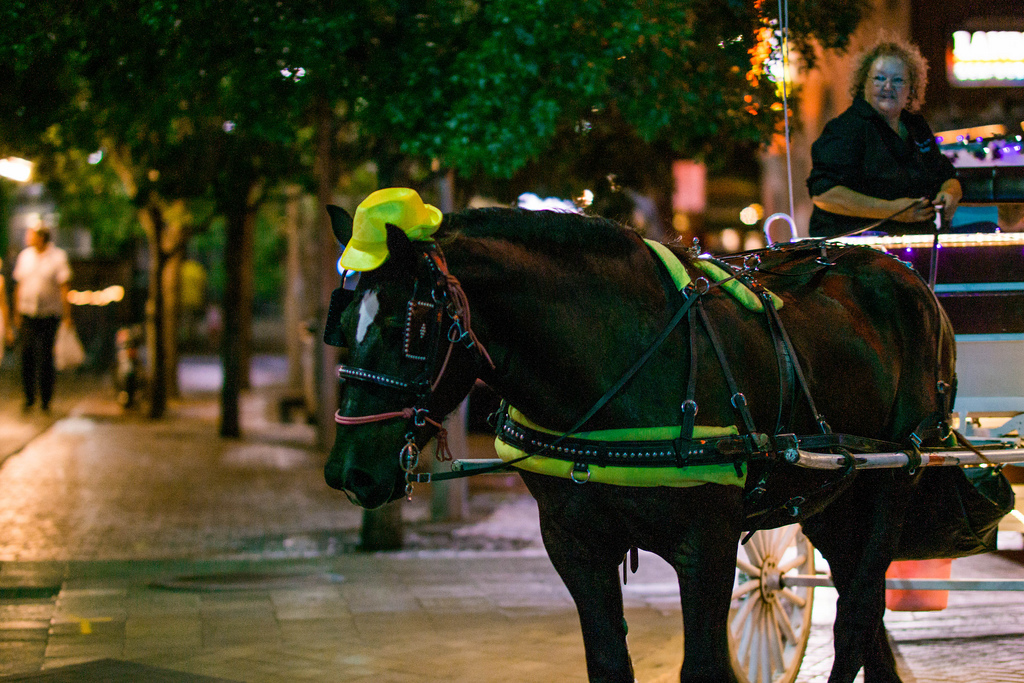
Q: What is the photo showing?
A: It is showing a street.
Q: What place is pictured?
A: It is a street.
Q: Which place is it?
A: It is a street.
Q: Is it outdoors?
A: Yes, it is outdoors.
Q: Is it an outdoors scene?
A: Yes, it is outdoors.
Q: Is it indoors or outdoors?
A: It is outdoors.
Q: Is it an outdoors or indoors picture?
A: It is outdoors.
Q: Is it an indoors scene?
A: No, it is outdoors.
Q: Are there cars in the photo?
A: No, there are no cars.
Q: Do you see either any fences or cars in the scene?
A: No, there are no cars or fences.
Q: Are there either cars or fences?
A: No, there are no cars or fences.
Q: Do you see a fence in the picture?
A: No, there are no fences.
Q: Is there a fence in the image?
A: No, there are no fences.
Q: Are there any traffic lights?
A: No, there are no traffic lights.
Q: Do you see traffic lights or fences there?
A: No, there are no traffic lights or fences.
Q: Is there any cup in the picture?
A: No, there are no cups.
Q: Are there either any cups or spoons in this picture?
A: No, there are no cups or spoons.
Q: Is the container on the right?
A: Yes, the container is on the right of the image.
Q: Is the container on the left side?
A: No, the container is on the right of the image.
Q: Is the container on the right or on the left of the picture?
A: The container is on the right of the image.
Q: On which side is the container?
A: The container is on the right of the image.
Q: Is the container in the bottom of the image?
A: Yes, the container is in the bottom of the image.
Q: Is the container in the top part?
A: No, the container is in the bottom of the image.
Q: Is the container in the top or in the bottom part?
A: The container is in the bottom of the image.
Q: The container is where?
A: The container is on the street.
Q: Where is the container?
A: The container is on the street.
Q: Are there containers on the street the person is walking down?
A: Yes, there is a container on the street.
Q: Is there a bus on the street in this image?
A: No, there is a container on the street.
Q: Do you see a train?
A: No, there are no trains.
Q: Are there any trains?
A: No, there are no trains.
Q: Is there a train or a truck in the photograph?
A: No, there are no trains or trucks.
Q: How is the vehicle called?
A: The vehicle is a carriage.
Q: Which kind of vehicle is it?
A: The vehicle is a carriage.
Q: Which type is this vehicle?
A: That is a carriage.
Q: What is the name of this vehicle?
A: That is a carriage.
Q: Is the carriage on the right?
A: Yes, the carriage is on the right of the image.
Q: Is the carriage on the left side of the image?
A: No, the carriage is on the right of the image.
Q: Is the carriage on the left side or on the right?
A: The carriage is on the right of the image.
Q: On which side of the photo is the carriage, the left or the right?
A: The carriage is on the right of the image.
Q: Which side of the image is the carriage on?
A: The carriage is on the right of the image.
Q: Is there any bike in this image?
A: No, there are no bikes.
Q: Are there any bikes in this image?
A: No, there are no bikes.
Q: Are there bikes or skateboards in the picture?
A: No, there are no bikes or skateboards.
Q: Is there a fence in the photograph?
A: No, there are no fences.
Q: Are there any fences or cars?
A: No, there are no fences or cars.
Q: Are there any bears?
A: No, there are no bears.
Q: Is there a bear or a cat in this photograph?
A: No, there are no bears or cats.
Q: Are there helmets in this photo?
A: No, there are no helmets.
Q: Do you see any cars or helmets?
A: No, there are no helmets or cars.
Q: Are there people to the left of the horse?
A: Yes, there is a person to the left of the horse.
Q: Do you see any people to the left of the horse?
A: Yes, there is a person to the left of the horse.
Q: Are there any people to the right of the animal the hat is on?
A: No, the person is to the left of the horse.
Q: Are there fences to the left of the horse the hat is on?
A: No, there is a person to the left of the horse.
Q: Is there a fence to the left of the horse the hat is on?
A: No, there is a person to the left of the horse.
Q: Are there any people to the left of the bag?
A: Yes, there is a person to the left of the bag.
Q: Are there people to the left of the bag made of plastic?
A: Yes, there is a person to the left of the bag.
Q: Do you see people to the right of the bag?
A: No, the person is to the left of the bag.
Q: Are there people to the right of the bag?
A: No, the person is to the left of the bag.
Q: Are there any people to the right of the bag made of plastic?
A: No, the person is to the left of the bag.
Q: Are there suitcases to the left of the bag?
A: No, there is a person to the left of the bag.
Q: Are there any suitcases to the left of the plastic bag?
A: No, there is a person to the left of the bag.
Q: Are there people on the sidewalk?
A: Yes, there is a person on the sidewalk.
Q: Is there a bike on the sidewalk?
A: No, there is a person on the sidewalk.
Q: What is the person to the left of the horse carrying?
A: The person is carrying a bag.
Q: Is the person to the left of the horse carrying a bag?
A: Yes, the person is carrying a bag.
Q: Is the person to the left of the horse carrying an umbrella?
A: No, the person is carrying a bag.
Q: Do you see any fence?
A: No, there are no fences.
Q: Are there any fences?
A: No, there are no fences.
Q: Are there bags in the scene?
A: Yes, there is a bag.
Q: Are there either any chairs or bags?
A: Yes, there is a bag.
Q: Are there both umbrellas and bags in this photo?
A: No, there is a bag but no umbrellas.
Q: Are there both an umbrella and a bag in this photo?
A: No, there is a bag but no umbrellas.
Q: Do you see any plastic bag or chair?
A: Yes, there is a plastic bag.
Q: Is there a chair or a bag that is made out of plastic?
A: Yes, the bag is made of plastic.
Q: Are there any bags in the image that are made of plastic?
A: Yes, there is a bag that is made of plastic.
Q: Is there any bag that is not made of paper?
A: Yes, there is a bag that is made of plastic.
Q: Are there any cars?
A: No, there are no cars.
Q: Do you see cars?
A: No, there are no cars.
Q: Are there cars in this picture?
A: No, there are no cars.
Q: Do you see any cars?
A: No, there are no cars.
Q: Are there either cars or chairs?
A: No, there are no cars or chairs.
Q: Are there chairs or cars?
A: No, there are no cars or chairs.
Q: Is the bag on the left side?
A: Yes, the bag is on the left of the image.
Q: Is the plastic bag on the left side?
A: Yes, the bag is on the left of the image.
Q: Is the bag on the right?
A: No, the bag is on the left of the image.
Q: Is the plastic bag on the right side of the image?
A: No, the bag is on the left of the image.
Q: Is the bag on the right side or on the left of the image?
A: The bag is on the left of the image.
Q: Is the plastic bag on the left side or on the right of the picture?
A: The bag is on the left of the image.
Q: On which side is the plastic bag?
A: The bag is on the left of the image.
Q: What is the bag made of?
A: The bag is made of plastic.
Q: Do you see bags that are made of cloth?
A: No, there is a bag but it is made of plastic.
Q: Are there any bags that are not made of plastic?
A: No, there is a bag but it is made of plastic.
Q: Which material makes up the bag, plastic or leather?
A: The bag is made of plastic.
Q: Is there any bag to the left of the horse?
A: Yes, there is a bag to the left of the horse.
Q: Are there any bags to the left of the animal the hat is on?
A: Yes, there is a bag to the left of the horse.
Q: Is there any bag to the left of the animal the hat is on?
A: Yes, there is a bag to the left of the horse.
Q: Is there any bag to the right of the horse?
A: No, the bag is to the left of the horse.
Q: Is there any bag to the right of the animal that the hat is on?
A: No, the bag is to the left of the horse.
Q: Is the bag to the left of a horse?
A: Yes, the bag is to the left of a horse.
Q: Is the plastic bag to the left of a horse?
A: Yes, the bag is to the left of a horse.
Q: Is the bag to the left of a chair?
A: No, the bag is to the left of a horse.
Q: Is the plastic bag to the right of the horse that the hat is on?
A: No, the bag is to the left of the horse.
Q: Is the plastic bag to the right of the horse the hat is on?
A: No, the bag is to the left of the horse.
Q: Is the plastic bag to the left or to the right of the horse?
A: The bag is to the left of the horse.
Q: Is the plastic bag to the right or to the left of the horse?
A: The bag is to the left of the horse.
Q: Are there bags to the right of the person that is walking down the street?
A: Yes, there is a bag to the right of the person.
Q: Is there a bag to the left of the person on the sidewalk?
A: No, the bag is to the right of the person.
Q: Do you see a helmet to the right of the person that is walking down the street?
A: No, there is a bag to the right of the person.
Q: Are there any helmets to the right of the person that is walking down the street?
A: No, there is a bag to the right of the person.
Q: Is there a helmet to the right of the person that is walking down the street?
A: No, there is a bag to the right of the person.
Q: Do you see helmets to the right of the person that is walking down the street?
A: No, there is a bag to the right of the person.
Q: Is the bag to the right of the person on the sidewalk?
A: Yes, the bag is to the right of the person.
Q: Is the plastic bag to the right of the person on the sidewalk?
A: Yes, the bag is to the right of the person.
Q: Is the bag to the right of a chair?
A: No, the bag is to the right of the person.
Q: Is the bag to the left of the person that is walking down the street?
A: No, the bag is to the right of the person.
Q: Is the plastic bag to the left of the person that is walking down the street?
A: No, the bag is to the right of the person.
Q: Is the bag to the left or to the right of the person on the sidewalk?
A: The bag is to the right of the person.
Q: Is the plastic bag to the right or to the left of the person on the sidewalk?
A: The bag is to the right of the person.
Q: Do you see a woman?
A: Yes, there is a woman.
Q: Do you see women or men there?
A: Yes, there is a woman.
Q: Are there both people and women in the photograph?
A: Yes, there are both a woman and a person.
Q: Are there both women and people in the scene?
A: Yes, there are both a woman and a person.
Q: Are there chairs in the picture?
A: No, there are no chairs.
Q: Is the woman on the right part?
A: Yes, the woman is on the right of the image.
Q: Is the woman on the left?
A: No, the woman is on the right of the image.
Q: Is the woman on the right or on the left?
A: The woman is on the right of the image.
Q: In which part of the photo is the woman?
A: The woman is on the right of the image.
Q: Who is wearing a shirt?
A: The woman is wearing a shirt.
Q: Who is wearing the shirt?
A: The woman is wearing a shirt.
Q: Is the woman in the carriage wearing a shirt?
A: Yes, the woman is wearing a shirt.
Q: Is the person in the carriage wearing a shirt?
A: Yes, the woman is wearing a shirt.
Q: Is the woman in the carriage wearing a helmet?
A: No, the woman is wearing a shirt.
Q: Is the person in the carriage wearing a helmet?
A: No, the woman is wearing a shirt.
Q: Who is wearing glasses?
A: The woman is wearing glasses.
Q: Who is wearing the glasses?
A: The woman is wearing glasses.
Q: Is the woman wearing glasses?
A: Yes, the woman is wearing glasses.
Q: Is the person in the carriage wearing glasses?
A: Yes, the woman is wearing glasses.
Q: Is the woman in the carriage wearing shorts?
A: No, the woman is wearing glasses.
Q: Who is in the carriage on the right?
A: The woman is in the carriage.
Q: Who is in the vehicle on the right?
A: The woman is in the carriage.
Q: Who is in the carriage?
A: The woman is in the carriage.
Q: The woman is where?
A: The woman is in the carriage.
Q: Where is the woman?
A: The woman is in the carriage.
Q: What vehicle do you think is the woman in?
A: The woman is in the carriage.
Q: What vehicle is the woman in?
A: The woman is in the carriage.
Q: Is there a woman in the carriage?
A: Yes, there is a woman in the carriage.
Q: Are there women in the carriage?
A: Yes, there is a woman in the carriage.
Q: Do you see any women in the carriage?
A: Yes, there is a woman in the carriage.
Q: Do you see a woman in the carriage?
A: Yes, there is a woman in the carriage.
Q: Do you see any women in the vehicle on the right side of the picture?
A: Yes, there is a woman in the carriage.